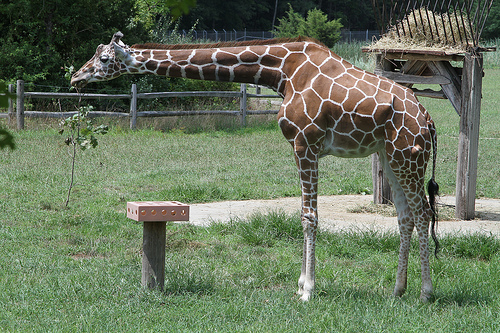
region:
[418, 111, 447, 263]
The tail of the giraffe.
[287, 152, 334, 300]
The two front legs of the giraffe.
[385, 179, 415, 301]
The back left leg of the giraffe.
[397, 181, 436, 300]
The back right leg of the giraffe.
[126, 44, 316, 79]
The neck of the giraffe.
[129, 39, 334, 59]
The giraffe's mane hair on its neck.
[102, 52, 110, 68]
The eye of the giraffe.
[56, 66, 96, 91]
The nose and mouth area of the giraffe.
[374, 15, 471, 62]
The hay behind the giraffe on the wooden posts.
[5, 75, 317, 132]
The wooden post fence surrounding the area where the giraffe is standing.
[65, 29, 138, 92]
head of a giraffe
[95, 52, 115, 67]
eye of a giraffe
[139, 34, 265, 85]
neck of a giraffe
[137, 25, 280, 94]
long neck of a giraffe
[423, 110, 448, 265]
tail of a giraffe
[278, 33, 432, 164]
body of a giraffe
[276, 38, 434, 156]
strong body of giraffe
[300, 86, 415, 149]
spots on a giraffe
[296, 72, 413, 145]
brown spots on giraffe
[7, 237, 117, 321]
patch of green grass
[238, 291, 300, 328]
The grass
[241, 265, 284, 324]
The grass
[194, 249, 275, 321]
The grass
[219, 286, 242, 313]
The grass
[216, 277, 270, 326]
The grass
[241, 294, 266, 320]
The grass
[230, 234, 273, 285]
The grass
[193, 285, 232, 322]
The grass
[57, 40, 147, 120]
giraffe eating small tree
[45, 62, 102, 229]
small tree in the ground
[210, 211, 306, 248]
tufts of green grass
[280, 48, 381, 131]
brown spots of a giraffe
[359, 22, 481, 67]
tan hay in holder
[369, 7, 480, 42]
metal grid holding hay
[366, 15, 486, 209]
wooden feeder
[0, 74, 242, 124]
brown wooden short fence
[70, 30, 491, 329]
giraffe standing on grass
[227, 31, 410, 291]
A giraffe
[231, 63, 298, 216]
A giraffe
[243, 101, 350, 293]
A giraffe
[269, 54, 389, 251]
A giraffe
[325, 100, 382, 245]
A giraffe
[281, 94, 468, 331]
A giraffe